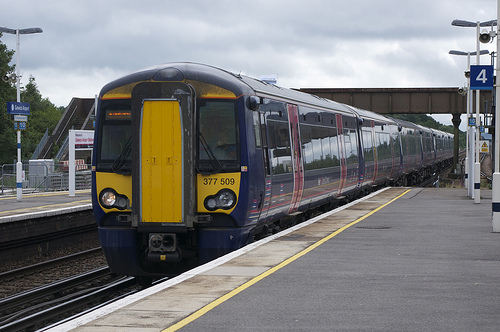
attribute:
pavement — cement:
[44, 184, 499, 330]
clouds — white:
[2, 2, 489, 89]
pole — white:
[12, 136, 29, 200]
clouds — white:
[428, 57, 448, 77]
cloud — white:
[73, 8, 167, 41]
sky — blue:
[29, 3, 489, 85]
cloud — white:
[372, 40, 462, 87]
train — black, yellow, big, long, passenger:
[87, 59, 457, 275]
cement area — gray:
[320, 232, 444, 324]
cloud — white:
[291, 2, 498, 34]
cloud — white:
[67, 14, 268, 70]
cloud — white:
[384, 38, 463, 83]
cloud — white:
[310, 50, 359, 80]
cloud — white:
[229, 52, 304, 78]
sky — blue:
[1, 0, 497, 130]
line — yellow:
[166, 187, 411, 330]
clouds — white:
[404, 19, 439, 32]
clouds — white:
[58, 10, 303, 60]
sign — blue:
[468, 62, 494, 89]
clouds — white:
[230, 16, 430, 74]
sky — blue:
[0, 2, 496, 117]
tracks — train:
[3, 242, 128, 308]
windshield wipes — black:
[107, 130, 220, 174]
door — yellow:
[131, 91, 196, 225]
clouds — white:
[321, 32, 403, 73]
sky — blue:
[10, 0, 494, 91]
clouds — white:
[268, 5, 458, 97]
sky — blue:
[262, 11, 478, 92]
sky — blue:
[254, 4, 484, 82]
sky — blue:
[130, 6, 482, 72]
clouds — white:
[73, 6, 483, 87]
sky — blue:
[92, 5, 483, 88]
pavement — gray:
[170, 184, 497, 329]